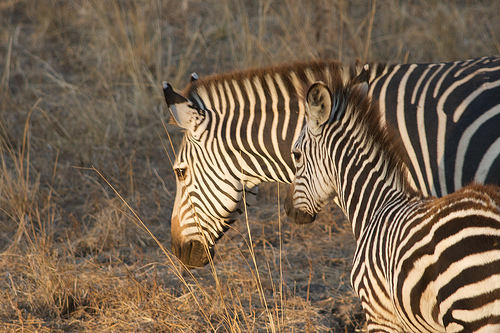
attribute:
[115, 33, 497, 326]
zebras — adult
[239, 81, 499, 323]
zebra — baby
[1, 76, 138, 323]
grass — brown, dead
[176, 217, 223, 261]
nose — black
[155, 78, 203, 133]
ear — black, white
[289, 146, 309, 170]
eye — dark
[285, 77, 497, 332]
zebra — baby, baby zebra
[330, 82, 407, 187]
mane — striped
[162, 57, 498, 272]
zebra — adult zebra, adult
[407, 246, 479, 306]
strips — black, white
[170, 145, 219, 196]
eye — dark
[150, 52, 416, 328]
zebra — adult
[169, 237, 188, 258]
snout — black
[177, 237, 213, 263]
mouth — black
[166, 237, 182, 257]
snout — black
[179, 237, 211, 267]
mouth — black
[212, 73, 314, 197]
neck — striped, black and white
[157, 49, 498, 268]
mother — zebra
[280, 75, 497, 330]
baby — zebra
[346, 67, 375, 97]
ear — right ear